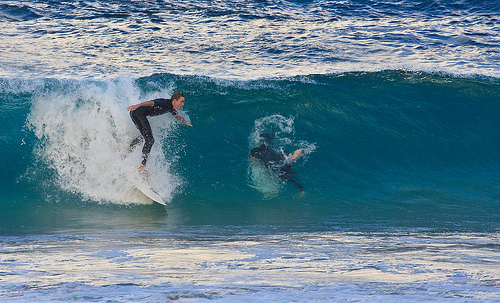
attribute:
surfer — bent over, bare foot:
[119, 88, 192, 157]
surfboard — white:
[109, 153, 164, 197]